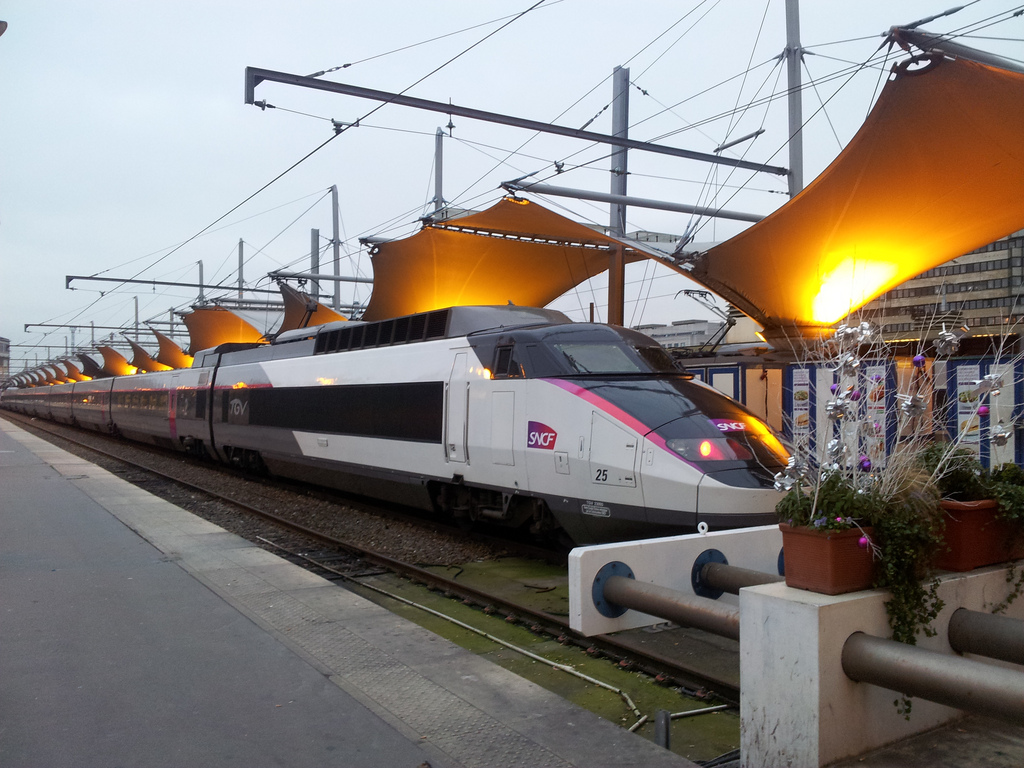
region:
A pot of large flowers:
[781, 329, 1004, 586]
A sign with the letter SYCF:
[516, 416, 564, 455]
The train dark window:
[552, 328, 685, 379]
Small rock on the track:
[99, 464, 467, 564]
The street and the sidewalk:
[4, 576, 516, 763]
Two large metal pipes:
[848, 609, 1022, 715]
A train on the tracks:
[3, 304, 798, 545]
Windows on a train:
[520, 330, 683, 381]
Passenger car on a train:
[109, 338, 250, 460]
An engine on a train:
[214, 301, 800, 549]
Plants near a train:
[771, 458, 946, 675]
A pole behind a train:
[593, 60, 635, 324]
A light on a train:
[689, 428, 722, 479]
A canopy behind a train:
[354, 193, 699, 317]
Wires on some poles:
[634, 48, 884, 159]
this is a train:
[0, 265, 858, 626]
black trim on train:
[488, 276, 784, 504]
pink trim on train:
[540, 376, 678, 481]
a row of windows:
[11, 374, 198, 431]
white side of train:
[258, 336, 720, 549]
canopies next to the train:
[0, 9, 1016, 398]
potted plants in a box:
[763, 285, 1008, 671]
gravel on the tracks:
[49, 392, 464, 627]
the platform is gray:
[5, 421, 566, 764]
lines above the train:
[8, 3, 1012, 335]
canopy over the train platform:
[691, 40, 1018, 341]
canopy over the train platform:
[257, 264, 340, 328]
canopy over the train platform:
[166, 289, 268, 347]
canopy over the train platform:
[143, 305, 197, 376]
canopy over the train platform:
[114, 321, 163, 375]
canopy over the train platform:
[92, 330, 132, 370]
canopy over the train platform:
[71, 337, 103, 380]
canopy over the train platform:
[59, 345, 86, 385]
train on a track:
[8, 310, 802, 564]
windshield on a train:
[524, 328, 684, 389]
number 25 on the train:
[588, 465, 612, 489]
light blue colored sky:
[2, 4, 1023, 378]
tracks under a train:
[12, 404, 766, 721]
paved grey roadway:
[2, 420, 437, 763]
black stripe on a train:
[5, 376, 458, 449]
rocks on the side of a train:
[6, 402, 504, 584]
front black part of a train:
[458, 298, 812, 492]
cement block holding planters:
[730, 553, 1022, 759]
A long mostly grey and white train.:
[3, 303, 792, 560]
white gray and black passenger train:
[181, 320, 766, 530]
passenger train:
[84, 323, 771, 521]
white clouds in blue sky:
[61, 174, 142, 238]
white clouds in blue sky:
[260, 133, 377, 188]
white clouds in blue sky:
[5, 186, 101, 282]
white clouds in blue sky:
[96, 37, 151, 136]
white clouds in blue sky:
[17, 72, 201, 174]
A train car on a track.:
[220, 291, 796, 551]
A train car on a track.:
[100, 355, 238, 458]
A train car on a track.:
[69, 358, 127, 447]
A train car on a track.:
[22, 377, 49, 403]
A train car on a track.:
[9, 384, 26, 403]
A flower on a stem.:
[859, 450, 875, 474]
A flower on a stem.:
[853, 531, 857, 535]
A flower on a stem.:
[828, 387, 845, 411]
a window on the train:
[347, 395, 352, 409]